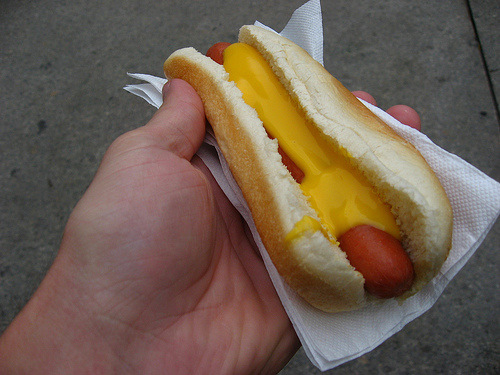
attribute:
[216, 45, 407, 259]
mustard — yellow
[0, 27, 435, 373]
hand — human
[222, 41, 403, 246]
mustard — yellow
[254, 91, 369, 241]
cheese — cheddar, sauce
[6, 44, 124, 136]
counter — grey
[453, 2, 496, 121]
streak — dark  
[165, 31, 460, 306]
hotdog bun — half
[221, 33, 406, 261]
cheese — melted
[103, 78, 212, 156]
thumb — Clutching 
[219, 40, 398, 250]
sauce — melted, nacho cheese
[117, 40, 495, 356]
napkin — rectangular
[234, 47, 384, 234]
cheese — melted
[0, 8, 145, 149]
pavement — gray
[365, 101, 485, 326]
napkin — white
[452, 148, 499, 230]
napkin — white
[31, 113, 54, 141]
spot — dark grey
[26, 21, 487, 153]
sidewalk — paved, gray